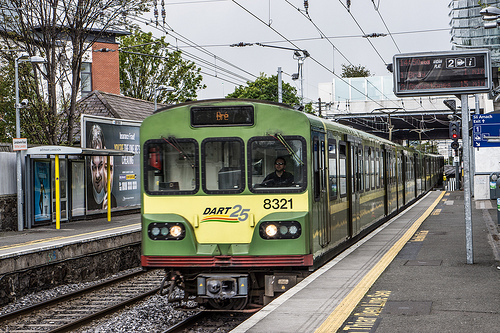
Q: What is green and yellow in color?
A: A train.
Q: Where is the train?
A: Railway Station.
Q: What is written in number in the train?
A: 8321.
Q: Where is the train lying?
A: On the track.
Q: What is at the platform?
A: Ads.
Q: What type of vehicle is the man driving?
A: Subway train.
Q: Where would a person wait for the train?
A: Under small shelter on platform.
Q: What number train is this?
A: 8321.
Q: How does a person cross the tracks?
A: Glass overpass.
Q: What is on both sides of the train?
A: Platform.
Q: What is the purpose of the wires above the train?
A: Runs train.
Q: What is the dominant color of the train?
A: Green.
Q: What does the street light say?
A: Red for stop.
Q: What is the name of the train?
A: Dart 25.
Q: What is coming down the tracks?
A: Train.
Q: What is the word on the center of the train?
A: Dart.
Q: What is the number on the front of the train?
A: 25.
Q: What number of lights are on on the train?
A: 2.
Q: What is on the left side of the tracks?
A: Billboard.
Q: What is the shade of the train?
A: Green and yellow.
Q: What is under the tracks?
A: Gravel.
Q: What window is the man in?
A: Right.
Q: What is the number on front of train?
A: Number is 8321.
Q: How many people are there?
A: One.